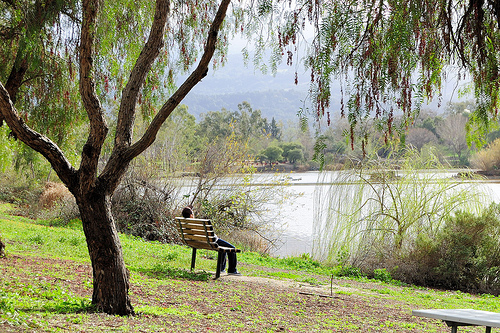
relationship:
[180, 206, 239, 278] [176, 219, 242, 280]
guy on bench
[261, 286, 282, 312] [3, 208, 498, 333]
patches on ground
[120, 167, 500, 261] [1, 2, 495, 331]
water in park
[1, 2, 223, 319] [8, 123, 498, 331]
trees in background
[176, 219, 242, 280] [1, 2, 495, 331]
bench in park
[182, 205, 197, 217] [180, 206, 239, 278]
head of man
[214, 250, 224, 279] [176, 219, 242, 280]
leg of bench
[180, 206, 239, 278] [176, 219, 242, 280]
man on bench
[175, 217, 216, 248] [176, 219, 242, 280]
back of bench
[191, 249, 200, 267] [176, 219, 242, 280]
leg of bench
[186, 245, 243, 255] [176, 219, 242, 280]
seat of bench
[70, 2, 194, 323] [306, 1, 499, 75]
tree with branches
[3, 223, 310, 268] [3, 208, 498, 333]
grass on ground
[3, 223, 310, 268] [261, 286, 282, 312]
grass has patches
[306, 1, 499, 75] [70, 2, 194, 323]
limbs on tree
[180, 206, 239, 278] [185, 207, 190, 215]
person with hair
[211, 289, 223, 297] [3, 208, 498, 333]
grass sprouts on ground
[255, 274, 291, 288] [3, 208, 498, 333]
dirt on ground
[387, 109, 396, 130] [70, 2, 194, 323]
blossoms on tree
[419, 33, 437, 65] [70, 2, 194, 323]
blooms on tree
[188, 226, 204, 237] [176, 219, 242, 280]
slats on bench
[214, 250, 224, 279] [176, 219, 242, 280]
support under bench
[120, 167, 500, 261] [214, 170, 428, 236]
plants along water